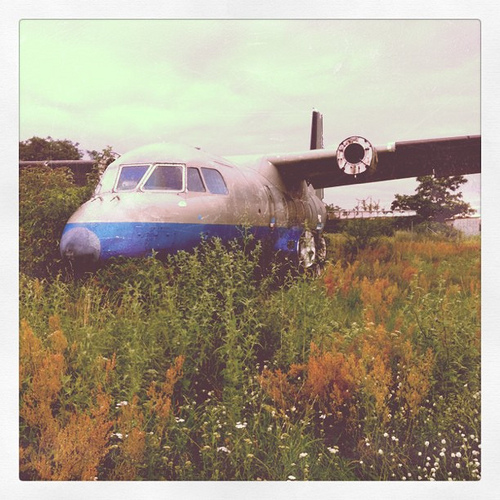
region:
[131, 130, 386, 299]
blue and white plane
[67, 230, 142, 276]
grey nose on plane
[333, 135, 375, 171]
grey engine on plane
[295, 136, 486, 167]
white wing on plane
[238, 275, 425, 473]
orange and green grass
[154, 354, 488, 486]
white buds on grass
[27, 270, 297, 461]
grass is green and weedy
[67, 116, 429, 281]
plane is downed in field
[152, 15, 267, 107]
grey and white sky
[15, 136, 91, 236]
tall green trees behind plane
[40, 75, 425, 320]
this is a plane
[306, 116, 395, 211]
this is a plane's engine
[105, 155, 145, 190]
this is a glass window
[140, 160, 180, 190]
this is a glass window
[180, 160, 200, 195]
this is a glass window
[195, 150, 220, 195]
this is a glass window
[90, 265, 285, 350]
this is green vegetation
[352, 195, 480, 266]
this is a building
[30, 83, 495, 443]
this is a white and blue plane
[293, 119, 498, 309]
this is a plane's wing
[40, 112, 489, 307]
blue and white plane in grass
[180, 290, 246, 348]
green plants and weeds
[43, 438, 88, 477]
brown plant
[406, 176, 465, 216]
tree with green leafs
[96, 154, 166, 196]
front windows from plane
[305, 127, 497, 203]
white plane wing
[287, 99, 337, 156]
white plane fin in sky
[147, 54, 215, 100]
light dark clouds in sky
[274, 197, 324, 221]
side windows on plane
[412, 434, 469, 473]
several white plant flowers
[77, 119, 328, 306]
plane downed in grass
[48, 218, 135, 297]
grey nose of plane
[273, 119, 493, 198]
white wing on plane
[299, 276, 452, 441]
orange plants in grass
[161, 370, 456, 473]
white flowering weeds in grass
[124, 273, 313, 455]
tall and weedy grass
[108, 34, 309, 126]
grey and cloudy sky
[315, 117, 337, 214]
black tail on plane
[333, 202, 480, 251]
grey building behind plane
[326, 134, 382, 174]
an engine on the plane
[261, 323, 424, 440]
brown bush in the grass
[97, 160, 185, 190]
windshield on the plane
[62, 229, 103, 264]
gray nose on the plane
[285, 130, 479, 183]
the plane wing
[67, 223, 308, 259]
blue stripe on the bottom of the plane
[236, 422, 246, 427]
small white flower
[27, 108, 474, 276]
an old plane parked in the field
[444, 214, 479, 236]
a shed behind the wing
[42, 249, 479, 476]
the weeds are over grown